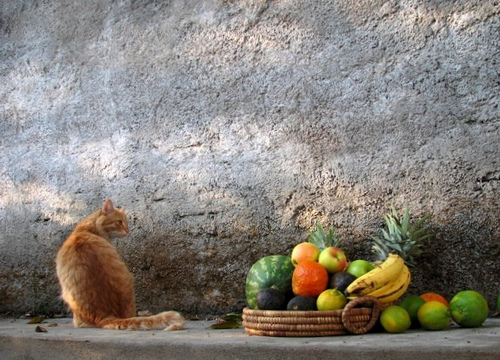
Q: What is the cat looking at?
A: The fruit.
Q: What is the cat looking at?
A: Fruit.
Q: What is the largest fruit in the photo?
A: Watermelon.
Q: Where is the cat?
A: By wall.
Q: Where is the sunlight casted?
A: On wall.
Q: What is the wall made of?
A: Cement.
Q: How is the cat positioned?
A: Sitting.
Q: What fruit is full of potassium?
A: Banana.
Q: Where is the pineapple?
A: Against wall.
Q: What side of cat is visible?
A: Back side.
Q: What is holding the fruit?
A: Basket.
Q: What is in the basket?
A: Fruit.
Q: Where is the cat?
A: Sidewalk.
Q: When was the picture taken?
A: Daytime.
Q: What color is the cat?
A: Orange and white.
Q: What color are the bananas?
A: Yellow.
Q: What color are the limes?
A: Green and yellow.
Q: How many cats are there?
A: One.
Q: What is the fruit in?
A: The basket.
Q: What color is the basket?
A: Brown.